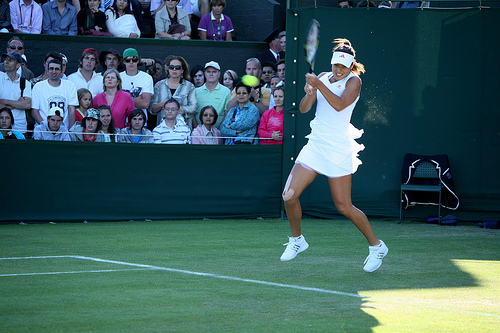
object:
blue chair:
[395, 151, 458, 226]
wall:
[285, 2, 497, 222]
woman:
[88, 104, 127, 142]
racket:
[301, 15, 323, 91]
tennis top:
[305, 70, 367, 142]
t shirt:
[315, 72, 362, 122]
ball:
[240, 72, 259, 87]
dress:
[290, 72, 369, 178]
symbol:
[335, 83, 342, 91]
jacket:
[398, 151, 458, 211]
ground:
[0, 217, 498, 331]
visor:
[329, 49, 356, 71]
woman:
[224, 83, 256, 144]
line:
[84, 252, 273, 284]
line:
[16, 267, 113, 274]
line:
[4, 252, 74, 261]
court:
[26, 230, 382, 322]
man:
[115, 107, 152, 142]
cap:
[115, 45, 146, 61]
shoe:
[360, 239, 389, 274]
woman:
[274, 37, 391, 274]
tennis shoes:
[352, 242, 395, 275]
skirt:
[294, 137, 369, 180]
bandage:
[281, 170, 296, 202]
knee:
[280, 187, 297, 202]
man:
[29, 58, 81, 129]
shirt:
[28, 79, 80, 128]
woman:
[190, 105, 220, 143]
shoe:
[278, 232, 310, 261]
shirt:
[217, 101, 261, 145]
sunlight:
[361, 257, 500, 333]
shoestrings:
[281, 235, 301, 248]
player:
[275, 38, 389, 275]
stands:
[0, 0, 288, 222]